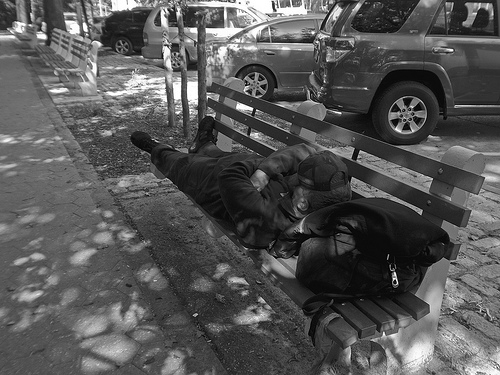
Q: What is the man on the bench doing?
A: Sleeping.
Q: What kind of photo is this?
A: Black and white.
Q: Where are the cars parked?
A: Parking lot.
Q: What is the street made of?
A: Cobblestone.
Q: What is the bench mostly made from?
A: Wood.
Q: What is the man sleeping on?
A: Backpack.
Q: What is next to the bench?
A: Sidewalk.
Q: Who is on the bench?
A: A man.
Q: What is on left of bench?
A: A pair of black tennis shoes.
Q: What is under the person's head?
A: A black bag and jacket.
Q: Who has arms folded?
A: Person sleeping on a bench.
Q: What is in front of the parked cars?
A: Benches on a sidewalk.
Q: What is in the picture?
A: Black and white image of a city street.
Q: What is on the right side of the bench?
A: Person's head resting on backpack.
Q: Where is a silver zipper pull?
A: Black backpack.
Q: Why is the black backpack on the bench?
A: Owner uses headrest.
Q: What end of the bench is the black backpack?
A: Right side picture.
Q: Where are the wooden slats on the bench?
A: Under black backpack.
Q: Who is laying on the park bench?
A: Tired man.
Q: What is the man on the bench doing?
A: Sleeping.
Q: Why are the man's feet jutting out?
A: Not enough room man and belongings.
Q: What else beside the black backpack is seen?
A: Man's jacket.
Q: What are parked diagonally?
A: Row of cars.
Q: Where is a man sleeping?
A: On a bench.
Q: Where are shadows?
A: On the ground.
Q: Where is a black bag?
A: On the bench.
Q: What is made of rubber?
A: Tires.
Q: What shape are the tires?
A: Round.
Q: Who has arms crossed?
A: Man sleeping.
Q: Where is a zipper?
A: On the bag.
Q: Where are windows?
A: On the vehicles.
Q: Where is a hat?
A: On man's face.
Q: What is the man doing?
A: Sleeping.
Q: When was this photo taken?
A: During the daytime.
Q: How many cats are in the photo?
A: Zero.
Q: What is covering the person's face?
A: A hat.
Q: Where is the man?
A: On the bench.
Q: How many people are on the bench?
A: One.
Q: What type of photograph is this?
A: Black and white.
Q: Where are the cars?
A: Parked along the street.